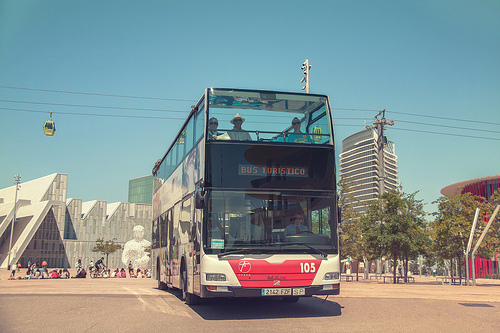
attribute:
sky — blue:
[7, 12, 498, 175]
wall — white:
[22, 175, 60, 206]